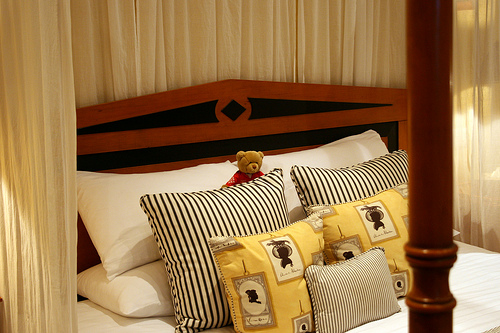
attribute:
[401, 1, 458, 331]
post — brown, wooden, red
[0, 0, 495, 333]
curtain — white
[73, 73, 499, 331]
bed — made, white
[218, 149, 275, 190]
teddy bear — brown, small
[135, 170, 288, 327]
pillow — black, white, striped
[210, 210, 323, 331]
pillow — yellow, decorative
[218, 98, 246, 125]
square — black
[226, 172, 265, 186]
shirt — red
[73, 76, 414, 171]
headboard — black, red, wooden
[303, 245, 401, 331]
pillow — smallest, small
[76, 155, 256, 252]
pillow — white, large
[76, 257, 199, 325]
pillow — flat, white